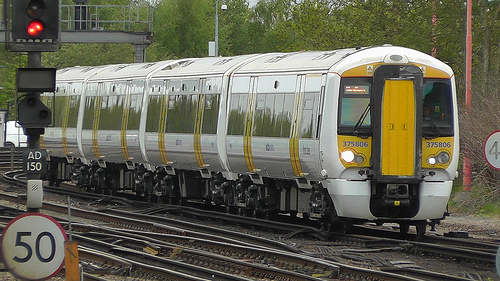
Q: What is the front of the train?
A: Yellow.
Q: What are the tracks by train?
A: Unused.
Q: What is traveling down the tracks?
A: The train.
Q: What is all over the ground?
A: Train tracks.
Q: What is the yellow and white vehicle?
A: A train.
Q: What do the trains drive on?
A: Train tracks.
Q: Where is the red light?
A: Top left corner.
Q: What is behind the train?
A: Trees.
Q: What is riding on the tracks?
A: A train.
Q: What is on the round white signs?
A: Numbers.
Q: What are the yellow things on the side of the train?
A: Doors.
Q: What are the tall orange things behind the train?
A: Poles.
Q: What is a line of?
A: Metal wheels.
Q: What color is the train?
A: White and yellow.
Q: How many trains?
A: One.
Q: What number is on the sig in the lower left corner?
A: 50.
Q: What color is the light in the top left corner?
A: Red.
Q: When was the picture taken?
A: During daytime.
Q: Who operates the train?
A: A train driver.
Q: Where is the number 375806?
A: On the the left and right sides in the front of the train.